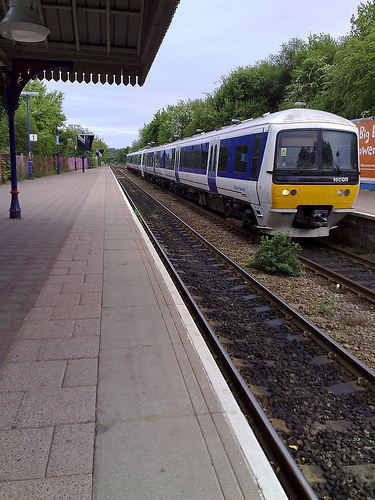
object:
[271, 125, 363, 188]
windshield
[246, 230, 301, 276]
bush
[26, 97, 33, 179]
pole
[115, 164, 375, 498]
dark gravel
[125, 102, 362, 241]
long train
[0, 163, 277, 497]
platform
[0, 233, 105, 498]
brick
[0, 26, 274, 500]
station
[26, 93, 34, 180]
light pole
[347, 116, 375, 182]
sign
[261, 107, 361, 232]
cockpit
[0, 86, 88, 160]
trees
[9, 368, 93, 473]
gray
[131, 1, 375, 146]
trees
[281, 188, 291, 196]
headlight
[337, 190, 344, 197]
headlight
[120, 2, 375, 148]
forest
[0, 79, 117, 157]
forest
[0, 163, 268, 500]
pavement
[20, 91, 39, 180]
lamp post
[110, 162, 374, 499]
track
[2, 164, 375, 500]
ground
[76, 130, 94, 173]
lamp post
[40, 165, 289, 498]
balcony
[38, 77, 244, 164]
background